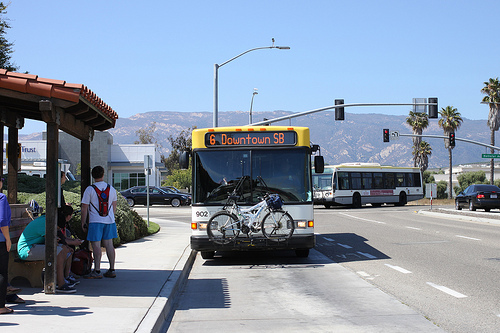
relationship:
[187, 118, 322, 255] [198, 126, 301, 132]
city bus with yellow trim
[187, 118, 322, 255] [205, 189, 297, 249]
city bus with bike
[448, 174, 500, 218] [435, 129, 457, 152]
car at stoplight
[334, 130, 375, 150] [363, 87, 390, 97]
mountains in background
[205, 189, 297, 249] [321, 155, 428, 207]
bike in front of bus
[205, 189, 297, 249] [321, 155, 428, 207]
bike in front bus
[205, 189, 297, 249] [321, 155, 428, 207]
bike in front of a bus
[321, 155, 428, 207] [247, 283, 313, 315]
bus on street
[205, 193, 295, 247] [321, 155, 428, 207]
bike on front of bus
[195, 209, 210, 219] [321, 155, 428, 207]
number 902 on bus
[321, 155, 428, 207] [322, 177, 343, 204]
bus making a turn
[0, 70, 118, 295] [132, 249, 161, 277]
bus stop on sidewalk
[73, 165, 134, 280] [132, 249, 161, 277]
man on sidewalk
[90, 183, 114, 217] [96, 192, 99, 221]
backpack on back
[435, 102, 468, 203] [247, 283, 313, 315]
palm tree by street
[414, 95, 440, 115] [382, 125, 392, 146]
sign on traffic signal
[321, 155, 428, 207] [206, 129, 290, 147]
bus has display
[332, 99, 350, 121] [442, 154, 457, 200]
streetlights are on pole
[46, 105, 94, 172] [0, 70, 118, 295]
bus stop at bus stop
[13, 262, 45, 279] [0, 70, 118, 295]
bench under bus stop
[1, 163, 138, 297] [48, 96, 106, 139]
people waiting at bus top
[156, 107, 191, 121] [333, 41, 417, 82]
mountain range near sky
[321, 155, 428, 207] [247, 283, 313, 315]
bus turning into street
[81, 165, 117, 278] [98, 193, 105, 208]
man wearing backpack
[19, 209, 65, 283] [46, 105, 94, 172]
person sitting at bus stop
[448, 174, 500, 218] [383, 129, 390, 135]
car stopped a light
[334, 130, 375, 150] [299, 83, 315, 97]
mountains in distance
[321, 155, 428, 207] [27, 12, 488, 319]
bus heading downtown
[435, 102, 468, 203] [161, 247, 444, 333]
palm tree on side of street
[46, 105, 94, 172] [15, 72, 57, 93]
bus stop has a roof